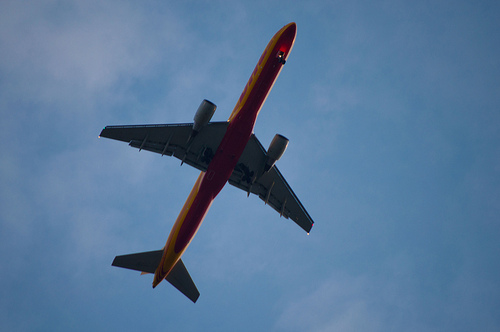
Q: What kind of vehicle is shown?
A: An airplane.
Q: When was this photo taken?
A: During the daytime.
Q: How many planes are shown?
A: One.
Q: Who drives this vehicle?
A: A pilot.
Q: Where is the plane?
A: Above the photographer.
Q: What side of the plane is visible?
A: Underneath side.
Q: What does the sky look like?
A: Mostly clear.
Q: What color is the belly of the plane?
A: Red.